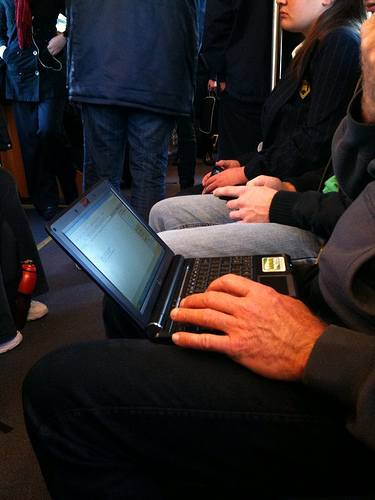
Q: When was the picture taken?
A: During a meeting.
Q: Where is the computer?
A: On his lap.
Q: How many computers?
A: One.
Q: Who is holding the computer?
A: Man.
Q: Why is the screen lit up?
A: The computer is on.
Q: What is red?
A: Water bottle on the left.